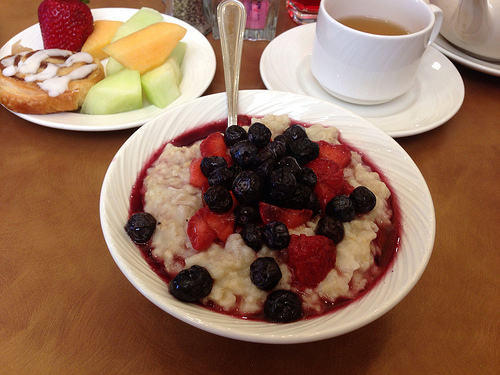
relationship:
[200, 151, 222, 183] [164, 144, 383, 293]
blueberry on top of oatmeal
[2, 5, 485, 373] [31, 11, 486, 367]
photograph of breakfast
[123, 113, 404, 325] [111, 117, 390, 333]
oatmeal with blueberries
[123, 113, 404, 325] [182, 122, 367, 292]
oatmeal with strawberries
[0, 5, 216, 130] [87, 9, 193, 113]
plate filled with fruit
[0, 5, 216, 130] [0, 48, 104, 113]
plate filled with pastry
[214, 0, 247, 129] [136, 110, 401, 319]
flat ware in oatmeal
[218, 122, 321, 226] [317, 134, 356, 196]
blueberries on top of strawberries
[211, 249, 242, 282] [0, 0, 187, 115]
oatmeal with fresh fruit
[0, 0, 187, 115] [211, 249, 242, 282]
fresh fruit on top of oatmeal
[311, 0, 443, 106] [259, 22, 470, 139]
cup on saucer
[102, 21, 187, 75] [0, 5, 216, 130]
cantaloupe on plate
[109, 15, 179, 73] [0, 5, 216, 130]
cantaloupe on plate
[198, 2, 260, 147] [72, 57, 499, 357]
flat ware in bowl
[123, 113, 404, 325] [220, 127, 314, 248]
oatmeal with fruit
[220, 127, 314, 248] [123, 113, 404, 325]
fruit on top oatmeal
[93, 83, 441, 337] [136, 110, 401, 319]
bowl of oatmeal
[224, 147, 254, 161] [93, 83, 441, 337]
blueberries in bowl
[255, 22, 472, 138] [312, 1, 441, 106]
plate under mug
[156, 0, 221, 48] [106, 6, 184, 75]
shaker by fruit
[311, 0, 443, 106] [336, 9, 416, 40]
cup has tea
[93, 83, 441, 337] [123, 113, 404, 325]
bowl of oatmeal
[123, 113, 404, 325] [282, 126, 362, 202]
oatmeal with fruit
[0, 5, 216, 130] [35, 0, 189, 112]
plate of fresh fruit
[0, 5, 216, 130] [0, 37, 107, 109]
plate of danish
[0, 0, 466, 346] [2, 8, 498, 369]
breakfast on table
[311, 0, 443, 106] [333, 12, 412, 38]
cup filled with tea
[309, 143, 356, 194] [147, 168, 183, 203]
strawberries on oatmeal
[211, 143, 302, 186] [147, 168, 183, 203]
blueberries on oatmeal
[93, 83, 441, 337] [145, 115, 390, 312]
bowl of oatmeal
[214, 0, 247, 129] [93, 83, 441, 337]
flat ware in bowl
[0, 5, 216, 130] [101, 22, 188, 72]
plate of melon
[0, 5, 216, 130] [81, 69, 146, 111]
plate of melon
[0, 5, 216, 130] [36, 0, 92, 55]
plate of strawberry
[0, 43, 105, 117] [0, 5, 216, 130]
pastry on plate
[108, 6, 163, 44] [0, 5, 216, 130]
cantaloupe on plate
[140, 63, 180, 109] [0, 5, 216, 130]
cantaloupe on plate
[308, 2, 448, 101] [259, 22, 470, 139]
cup on saucer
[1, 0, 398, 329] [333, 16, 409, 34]
breakfast with tea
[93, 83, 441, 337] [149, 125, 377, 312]
bowl of oatmeal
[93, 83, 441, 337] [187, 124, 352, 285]
bowl of fruit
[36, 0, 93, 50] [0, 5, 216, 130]
strawberry on plate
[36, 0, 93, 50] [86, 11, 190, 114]
strawberry with melon